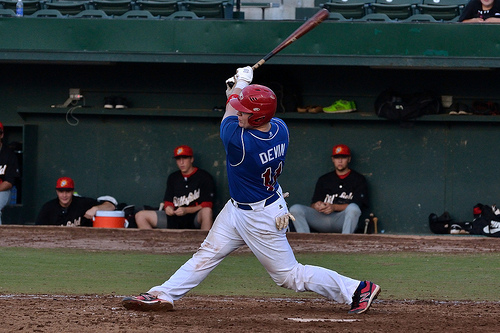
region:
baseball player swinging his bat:
[122, 10, 384, 316]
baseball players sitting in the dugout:
[37, 142, 370, 232]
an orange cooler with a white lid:
[91, 208, 125, 230]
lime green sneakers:
[323, 98, 356, 115]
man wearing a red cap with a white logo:
[54, 177, 74, 192]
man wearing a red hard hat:
[231, 83, 279, 128]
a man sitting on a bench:
[1, 122, 17, 214]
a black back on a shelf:
[373, 90, 422, 121]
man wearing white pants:
[151, 187, 363, 309]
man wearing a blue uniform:
[218, 113, 288, 200]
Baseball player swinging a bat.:
[120, 8, 380, 315]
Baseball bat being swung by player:
[221, 7, 332, 86]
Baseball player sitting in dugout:
[284, 140, 366, 232]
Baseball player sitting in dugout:
[132, 142, 212, 230]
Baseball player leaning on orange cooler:
[32, 177, 130, 229]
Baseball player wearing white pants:
[147, 199, 364, 306]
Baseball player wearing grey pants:
[289, 202, 361, 232]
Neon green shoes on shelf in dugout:
[322, 99, 354, 114]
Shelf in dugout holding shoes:
[5, 82, 491, 119]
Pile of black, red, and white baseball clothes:
[427, 199, 497, 239]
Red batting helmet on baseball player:
[224, 82, 279, 132]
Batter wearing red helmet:
[127, 63, 386, 314]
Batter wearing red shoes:
[122, 68, 382, 317]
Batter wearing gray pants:
[140, 62, 382, 315]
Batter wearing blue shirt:
[130, 65, 381, 317]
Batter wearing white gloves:
[133, 59, 388, 313]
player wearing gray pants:
[287, 144, 368, 233]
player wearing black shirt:
[289, 146, 370, 235]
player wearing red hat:
[292, 144, 367, 230]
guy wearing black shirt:
[132, 145, 212, 230]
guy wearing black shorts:
[137, 146, 214, 229]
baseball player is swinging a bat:
[197, 61, 311, 296]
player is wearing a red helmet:
[230, 81, 270, 118]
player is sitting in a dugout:
[151, 142, 218, 225]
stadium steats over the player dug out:
[106, 13, 467, 36]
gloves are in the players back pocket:
[277, 211, 295, 235]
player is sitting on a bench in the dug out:
[307, 138, 354, 240]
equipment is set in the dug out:
[429, 204, 495, 249]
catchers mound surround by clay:
[283, 301, 350, 332]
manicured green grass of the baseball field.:
[19, 250, 154, 303]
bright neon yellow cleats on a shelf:
[326, 97, 356, 114]